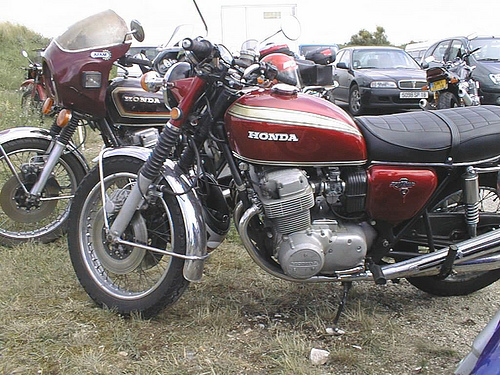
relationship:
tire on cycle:
[70, 132, 200, 340] [62, 140, 474, 335]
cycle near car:
[423, 46, 489, 126] [425, 34, 498, 105]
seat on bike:
[366, 98, 498, 161] [65, 35, 497, 333]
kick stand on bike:
[326, 282, 353, 333] [65, 35, 497, 333]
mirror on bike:
[268, 10, 308, 52] [65, 35, 497, 333]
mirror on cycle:
[119, 9, 157, 59] [1, 8, 222, 269]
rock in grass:
[308, 346, 329, 369] [5, 238, 497, 372]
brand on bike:
[238, 123, 307, 149] [65, 35, 497, 333]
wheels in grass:
[2, 119, 207, 326] [0, 202, 496, 372]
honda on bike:
[246, 129, 300, 143] [64, 37, 496, 326]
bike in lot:
[65, 35, 497, 333] [3, 9, 497, 329]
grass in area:
[4, 17, 488, 373] [5, 15, 498, 369]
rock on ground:
[294, 339, 336, 369] [6, 230, 498, 370]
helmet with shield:
[254, 45, 340, 101] [264, 58, 302, 88]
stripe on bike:
[229, 100, 357, 134] [65, 35, 497, 333]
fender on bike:
[83, 136, 216, 291] [65, 35, 497, 333]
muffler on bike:
[334, 223, 500, 293] [65, 35, 497, 333]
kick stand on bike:
[322, 265, 357, 329] [65, 35, 497, 333]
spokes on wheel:
[73, 171, 179, 302] [56, 138, 220, 321]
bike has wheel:
[65, 35, 497, 333] [56, 138, 220, 321]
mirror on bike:
[279, 10, 302, 42] [65, 35, 497, 333]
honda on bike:
[241, 122, 305, 152] [65, 35, 497, 333]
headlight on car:
[366, 76, 404, 97] [314, 40, 442, 118]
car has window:
[314, 40, 442, 118] [348, 42, 425, 77]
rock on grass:
[308, 346, 329, 369] [2, 126, 458, 372]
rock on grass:
[326, 326, 334, 336] [2, 126, 458, 372]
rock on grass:
[243, 327, 251, 336] [2, 126, 458, 372]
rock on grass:
[272, 308, 285, 319] [2, 126, 458, 372]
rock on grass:
[252, 317, 273, 332] [2, 126, 458, 372]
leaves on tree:
[344, 26, 393, 48] [334, 25, 412, 58]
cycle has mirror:
[0, 8, 176, 249] [118, 13, 155, 58]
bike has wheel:
[65, 35, 497, 333] [63, 143, 212, 330]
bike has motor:
[65, 35, 497, 333] [250, 163, 380, 281]